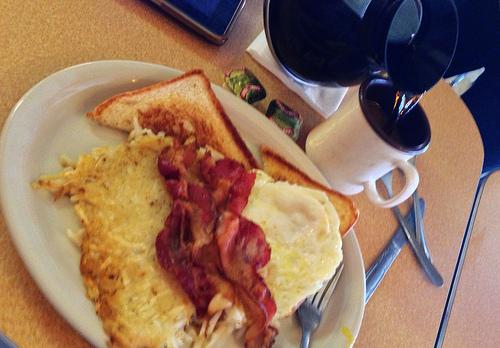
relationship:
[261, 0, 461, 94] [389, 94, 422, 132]
coffee pot pouring coffee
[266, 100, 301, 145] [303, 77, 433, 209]
pack of butter next to coffee mug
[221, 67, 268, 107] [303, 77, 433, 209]
pack of butter next to coffee mug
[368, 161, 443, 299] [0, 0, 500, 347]
silverware on table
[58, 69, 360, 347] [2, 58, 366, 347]
breakfast on plate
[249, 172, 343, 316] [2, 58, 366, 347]
egg on plate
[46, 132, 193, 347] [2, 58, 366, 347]
hash browns are on plate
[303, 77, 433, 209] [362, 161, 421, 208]
coffee mug has a handle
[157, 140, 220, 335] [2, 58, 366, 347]
bacon on plate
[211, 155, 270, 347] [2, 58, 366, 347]
bacon on plate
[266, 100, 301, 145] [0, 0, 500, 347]
pack of butter on table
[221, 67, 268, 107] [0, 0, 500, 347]
pack of butter on table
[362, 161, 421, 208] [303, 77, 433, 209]
handle on coffee mug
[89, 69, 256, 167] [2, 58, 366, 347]
toast on plate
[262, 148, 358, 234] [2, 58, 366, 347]
toast on plate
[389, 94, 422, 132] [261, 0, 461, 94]
coffee poured from coffee pot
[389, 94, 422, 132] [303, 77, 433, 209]
coffee poured into coffee mug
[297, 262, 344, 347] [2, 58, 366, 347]
fork on plate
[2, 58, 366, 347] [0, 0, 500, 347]
plate on table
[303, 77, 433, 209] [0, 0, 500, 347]
coffee mug on table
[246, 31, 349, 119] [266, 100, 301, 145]
napkin near pack of butter